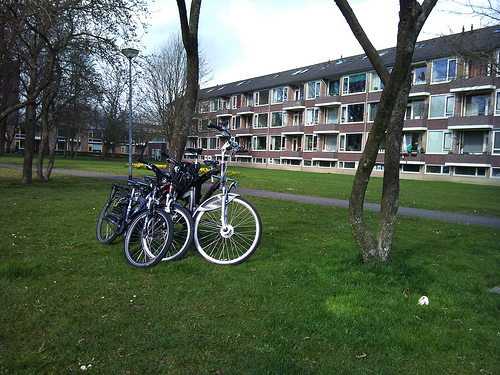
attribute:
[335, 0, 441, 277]
trunk — brown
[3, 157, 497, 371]
grass — green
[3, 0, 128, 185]
tree — bare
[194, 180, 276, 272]
tire — black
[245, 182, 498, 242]
cement — grey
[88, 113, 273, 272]
bikes — parked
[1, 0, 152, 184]
tree — distant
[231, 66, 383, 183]
building — distant